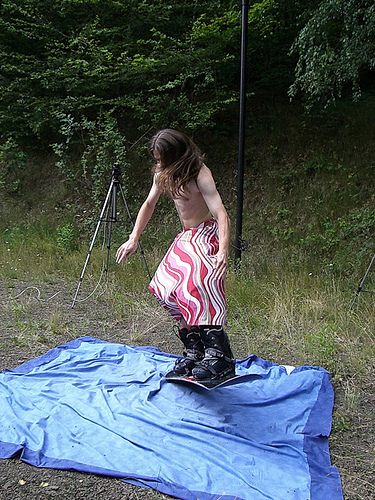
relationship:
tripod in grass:
[86, 181, 166, 308] [13, 241, 109, 286]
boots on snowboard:
[174, 327, 249, 377] [176, 368, 213, 397]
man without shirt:
[104, 133, 324, 401] [131, 160, 232, 224]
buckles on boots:
[201, 351, 220, 359] [174, 327, 249, 377]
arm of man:
[194, 169, 252, 274] [104, 133, 324, 401]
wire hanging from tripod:
[100, 210, 112, 290] [86, 181, 166, 308]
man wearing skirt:
[104, 133, 324, 401] [143, 226, 245, 339]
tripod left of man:
[86, 181, 166, 308] [104, 133, 324, 401]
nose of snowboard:
[161, 374, 213, 394] [176, 368, 213, 397]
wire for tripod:
[100, 210, 112, 290] [86, 181, 166, 308]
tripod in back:
[86, 181, 166, 308] [75, 193, 103, 202]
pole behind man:
[222, 8, 261, 262] [104, 133, 324, 401]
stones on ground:
[7, 475, 50, 487] [4, 469, 117, 499]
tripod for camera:
[86, 181, 166, 308] [98, 158, 131, 184]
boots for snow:
[174, 327, 249, 377] [184, 374, 258, 386]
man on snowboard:
[104, 133, 324, 401] [176, 368, 213, 397]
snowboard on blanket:
[176, 368, 213, 397] [11, 330, 345, 497]